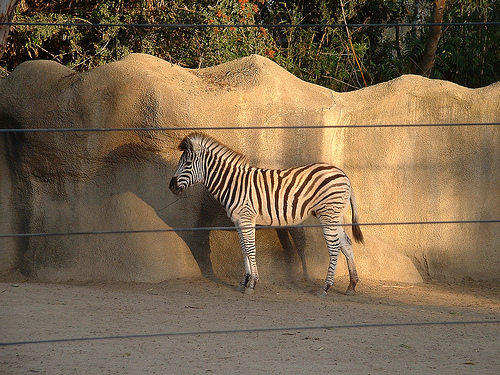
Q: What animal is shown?
A: Zebra.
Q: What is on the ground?
A: Dirt.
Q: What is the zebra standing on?
A: Dirt.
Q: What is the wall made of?
A: Cement.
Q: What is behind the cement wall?
A: Trees.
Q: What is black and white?
A: Zebra.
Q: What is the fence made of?
A: Wires.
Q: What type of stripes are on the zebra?
A: Vertical.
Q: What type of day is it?
A: Sunny.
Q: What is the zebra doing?
A: Standing.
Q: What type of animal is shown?
A: Zebra.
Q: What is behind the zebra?
A: Rock wall.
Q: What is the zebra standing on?
A: Dirt.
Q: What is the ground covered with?
A: Dirt.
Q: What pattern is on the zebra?
A: Stripes.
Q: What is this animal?
A: Zebra.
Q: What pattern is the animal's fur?
A: Striped.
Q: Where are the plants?
A: Other side of the fence.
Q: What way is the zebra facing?
A: The left.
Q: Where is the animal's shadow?
A: On the wall.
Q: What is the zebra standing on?
A: Dirt.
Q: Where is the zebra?
A: At a zoo.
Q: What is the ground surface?
A: Dirt.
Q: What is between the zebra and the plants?
A: The stone wall.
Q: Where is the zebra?
A: By the boulder.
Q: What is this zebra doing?
A: Standing still.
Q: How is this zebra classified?
A: As a mammal.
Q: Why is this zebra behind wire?
A: Zoo protection.